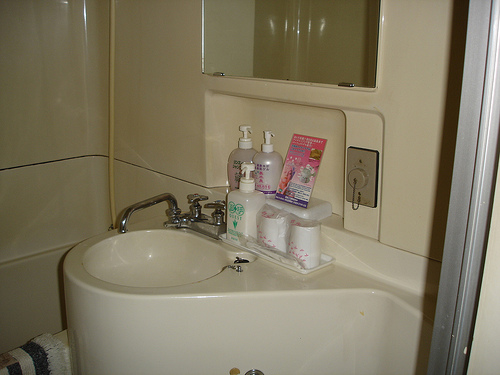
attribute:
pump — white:
[258, 127, 273, 152]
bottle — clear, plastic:
[252, 149, 282, 190]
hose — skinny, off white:
[105, 3, 118, 232]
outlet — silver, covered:
[344, 146, 383, 214]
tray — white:
[221, 222, 333, 272]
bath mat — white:
[6, 330, 63, 371]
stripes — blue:
[10, 339, 50, 373]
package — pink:
[278, 131, 326, 208]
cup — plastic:
[256, 213, 288, 257]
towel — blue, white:
[7, 330, 72, 373]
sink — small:
[58, 187, 438, 373]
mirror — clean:
[198, 2, 384, 92]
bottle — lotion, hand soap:
[227, 160, 267, 236]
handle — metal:
[183, 187, 207, 218]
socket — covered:
[345, 145, 377, 208]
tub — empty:
[1, 243, 78, 371]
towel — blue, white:
[7, 330, 67, 370]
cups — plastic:
[260, 208, 323, 268]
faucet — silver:
[114, 190, 181, 232]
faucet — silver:
[115, 190, 228, 240]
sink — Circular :
[66, 189, 252, 333]